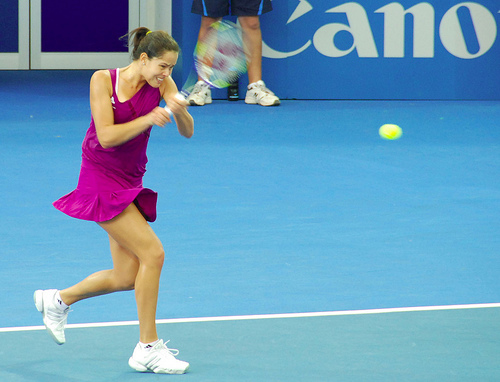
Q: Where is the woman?
A: On a tennis court.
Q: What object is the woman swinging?
A: A tennis racquet.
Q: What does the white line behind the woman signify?
A: Out of bounds.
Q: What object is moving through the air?
A: A tennis ball.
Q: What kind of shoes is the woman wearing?
A: White tennis shoes.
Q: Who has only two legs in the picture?
A: A male tennis player.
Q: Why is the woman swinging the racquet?
A: To hit the ball.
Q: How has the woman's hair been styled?
A: In a pony tail.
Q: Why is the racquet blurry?
A: The racquet is blurry because it is moving.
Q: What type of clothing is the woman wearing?
A: A jumper.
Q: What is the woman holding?
A: A tennis racket.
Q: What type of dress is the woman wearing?
A: A purple dress.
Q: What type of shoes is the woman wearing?
A: White tennis shoes.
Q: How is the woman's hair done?
A: In a ponytail.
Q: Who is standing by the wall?
A: A man.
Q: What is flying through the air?
A: The tennis ball.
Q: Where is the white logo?
A: Behind the woman.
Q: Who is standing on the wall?
A: Linesperson.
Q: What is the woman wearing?
A: Pink dress.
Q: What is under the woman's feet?
A: Tennis court.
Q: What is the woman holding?
A: Racquet.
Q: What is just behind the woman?
A: White line.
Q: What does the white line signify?
A: Out-of-bounds.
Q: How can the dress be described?
A: Short.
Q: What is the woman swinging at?
A: Tennis ball.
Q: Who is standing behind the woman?
A: Linesman.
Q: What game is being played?
A: Tennis.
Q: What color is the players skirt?
A: Purple.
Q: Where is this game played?
A: Court.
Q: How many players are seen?
A: One.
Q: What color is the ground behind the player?
A: Blue.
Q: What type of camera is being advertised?
A: Canon.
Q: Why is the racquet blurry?
A: It's moving.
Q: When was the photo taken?
A: During a game.